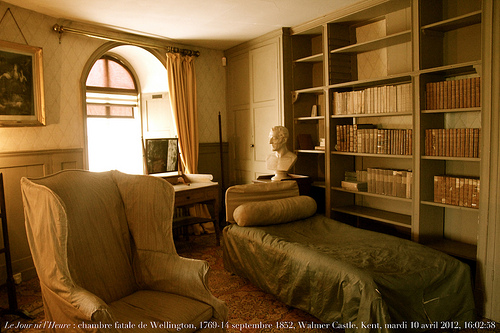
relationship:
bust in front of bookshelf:
[266, 125, 297, 181] [288, 0, 493, 317]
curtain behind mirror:
[165, 52, 216, 236] [141, 135, 190, 186]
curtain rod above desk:
[52, 23, 200, 57] [172, 181, 221, 246]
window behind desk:
[85, 55, 143, 175] [172, 181, 221, 246]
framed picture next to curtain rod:
[1, 7, 46, 127] [52, 23, 200, 57]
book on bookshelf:
[341, 179, 368, 189] [288, 0, 493, 317]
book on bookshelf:
[341, 186, 367, 192] [288, 0, 493, 317]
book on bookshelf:
[366, 167, 372, 193] [288, 0, 493, 317]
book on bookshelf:
[371, 168, 376, 194] [288, 0, 493, 317]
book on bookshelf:
[375, 170, 379, 194] [288, 0, 493, 317]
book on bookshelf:
[379, 170, 384, 195] [288, 0, 493, 317]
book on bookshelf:
[383, 170, 388, 196] [288, 0, 493, 317]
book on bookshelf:
[387, 170, 392, 196] [288, 0, 493, 317]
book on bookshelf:
[392, 170, 397, 196] [288, 0, 493, 317]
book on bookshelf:
[397, 171, 402, 198] [288, 0, 493, 317]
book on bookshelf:
[401, 171, 406, 199] [288, 0, 493, 317]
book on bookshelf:
[406, 171, 411, 198] [288, 0, 493, 317]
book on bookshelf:
[410, 171, 413, 199] [288, 0, 493, 317]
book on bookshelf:
[296, 133, 314, 149] [288, 0, 493, 317]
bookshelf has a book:
[288, 0, 493, 317] [296, 133, 314, 149]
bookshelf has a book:
[288, 0, 493, 317] [341, 179, 368, 189]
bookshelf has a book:
[288, 0, 493, 317] [341, 186, 367, 192]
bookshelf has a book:
[288, 0, 493, 317] [366, 167, 372, 193]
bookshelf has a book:
[288, 0, 493, 317] [371, 168, 376, 194]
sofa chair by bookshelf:
[222, 180, 474, 333] [288, 0, 493, 317]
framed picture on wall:
[1, 7, 46, 127] [0, 0, 230, 288]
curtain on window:
[165, 52, 216, 236] [85, 55, 143, 175]